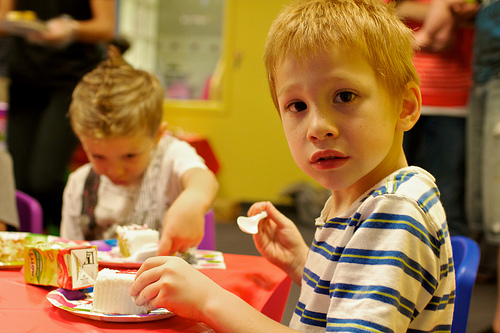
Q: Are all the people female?
A: No, they are both male and female.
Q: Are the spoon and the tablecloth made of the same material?
A: Yes, both the spoon and the tablecloth are made of plastic.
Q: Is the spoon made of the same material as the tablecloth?
A: Yes, both the spoon and the tablecloth are made of plastic.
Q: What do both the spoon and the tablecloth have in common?
A: The material, both the spoon and the tablecloth are plastic.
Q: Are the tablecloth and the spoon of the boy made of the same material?
A: Yes, both the tablecloth and the spoon are made of plastic.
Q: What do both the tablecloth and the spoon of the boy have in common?
A: The material, both the tablecloth and the spoon are plastic.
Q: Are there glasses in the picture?
A: No, there are no glasses.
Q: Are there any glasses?
A: No, there are no glasses.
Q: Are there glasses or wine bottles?
A: No, there are no glasses or wine bottles.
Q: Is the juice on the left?
A: Yes, the juice is on the left of the image.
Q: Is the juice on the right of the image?
A: No, the juice is on the left of the image.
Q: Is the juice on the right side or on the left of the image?
A: The juice is on the left of the image.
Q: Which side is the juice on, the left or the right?
A: The juice is on the left of the image.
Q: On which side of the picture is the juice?
A: The juice is on the left of the image.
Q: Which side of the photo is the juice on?
A: The juice is on the left of the image.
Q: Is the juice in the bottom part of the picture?
A: Yes, the juice is in the bottom of the image.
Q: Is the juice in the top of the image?
A: No, the juice is in the bottom of the image.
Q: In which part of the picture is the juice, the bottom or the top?
A: The juice is in the bottom of the image.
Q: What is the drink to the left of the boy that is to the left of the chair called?
A: The drink is juice.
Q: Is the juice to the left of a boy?
A: Yes, the juice is to the left of a boy.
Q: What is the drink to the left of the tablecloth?
A: The drink is juice.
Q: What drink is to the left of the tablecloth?
A: The drink is juice.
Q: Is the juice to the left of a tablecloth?
A: Yes, the juice is to the left of a tablecloth.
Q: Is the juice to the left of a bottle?
A: No, the juice is to the left of a tablecloth.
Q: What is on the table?
A: The juice is on the table.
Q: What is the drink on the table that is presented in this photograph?
A: The drink is juice.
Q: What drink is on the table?
A: The drink is juice.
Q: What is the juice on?
A: The juice is on the table.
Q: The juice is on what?
A: The juice is on the table.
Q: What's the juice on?
A: The juice is on the table.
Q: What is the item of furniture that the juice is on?
A: The piece of furniture is a table.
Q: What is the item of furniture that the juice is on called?
A: The piece of furniture is a table.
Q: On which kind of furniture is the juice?
A: The juice is on the table.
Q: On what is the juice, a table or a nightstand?
A: The juice is on a table.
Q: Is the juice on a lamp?
A: No, the juice is on the table.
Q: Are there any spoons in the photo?
A: Yes, there is a spoon.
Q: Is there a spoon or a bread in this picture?
A: Yes, there is a spoon.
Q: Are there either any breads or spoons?
A: Yes, there is a spoon.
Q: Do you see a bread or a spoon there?
A: Yes, there is a spoon.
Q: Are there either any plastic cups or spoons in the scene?
A: Yes, there is a plastic spoon.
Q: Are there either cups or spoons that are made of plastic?
A: Yes, the spoon is made of plastic.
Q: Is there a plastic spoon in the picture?
A: Yes, there is a spoon that is made of plastic.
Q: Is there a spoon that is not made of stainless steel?
A: Yes, there is a spoon that is made of plastic.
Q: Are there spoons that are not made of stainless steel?
A: Yes, there is a spoon that is made of plastic.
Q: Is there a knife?
A: No, there are no knives.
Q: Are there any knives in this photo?
A: No, there are no knives.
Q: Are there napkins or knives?
A: No, there are no knives or napkins.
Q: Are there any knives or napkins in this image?
A: No, there are no knives or napkins.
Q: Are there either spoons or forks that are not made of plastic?
A: No, there is a spoon but it is made of plastic.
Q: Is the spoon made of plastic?
A: Yes, the spoon is made of plastic.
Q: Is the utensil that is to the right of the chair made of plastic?
A: Yes, the spoon is made of plastic.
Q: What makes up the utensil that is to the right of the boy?
A: The spoon is made of plastic.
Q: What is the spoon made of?
A: The spoon is made of plastic.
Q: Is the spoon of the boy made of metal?
A: No, the spoon is made of plastic.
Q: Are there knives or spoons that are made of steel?
A: No, there is a spoon but it is made of plastic.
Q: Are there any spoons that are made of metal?
A: No, there is a spoon but it is made of plastic.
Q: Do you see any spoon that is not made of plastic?
A: No, there is a spoon but it is made of plastic.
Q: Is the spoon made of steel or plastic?
A: The spoon is made of plastic.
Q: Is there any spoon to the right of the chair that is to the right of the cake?
A: Yes, there is a spoon to the right of the chair.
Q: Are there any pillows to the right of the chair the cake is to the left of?
A: No, there is a spoon to the right of the chair.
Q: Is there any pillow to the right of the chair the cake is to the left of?
A: No, there is a spoon to the right of the chair.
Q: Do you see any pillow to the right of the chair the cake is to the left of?
A: No, there is a spoon to the right of the chair.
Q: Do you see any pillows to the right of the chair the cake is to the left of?
A: No, there is a spoon to the right of the chair.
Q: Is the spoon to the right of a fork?
A: No, the spoon is to the right of the chair.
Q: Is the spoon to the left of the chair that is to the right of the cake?
A: No, the spoon is to the right of the chair.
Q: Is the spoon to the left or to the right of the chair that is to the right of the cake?
A: The spoon is to the right of the chair.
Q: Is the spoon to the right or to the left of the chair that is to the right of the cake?
A: The spoon is to the right of the chair.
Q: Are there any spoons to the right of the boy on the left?
A: Yes, there is a spoon to the right of the boy.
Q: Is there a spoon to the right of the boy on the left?
A: Yes, there is a spoon to the right of the boy.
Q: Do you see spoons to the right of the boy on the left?
A: Yes, there is a spoon to the right of the boy.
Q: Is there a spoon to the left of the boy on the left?
A: No, the spoon is to the right of the boy.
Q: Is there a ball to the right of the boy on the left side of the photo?
A: No, there is a spoon to the right of the boy.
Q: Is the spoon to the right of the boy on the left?
A: Yes, the spoon is to the right of the boy.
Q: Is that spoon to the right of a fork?
A: No, the spoon is to the right of the boy.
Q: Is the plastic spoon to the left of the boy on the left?
A: No, the spoon is to the right of the boy.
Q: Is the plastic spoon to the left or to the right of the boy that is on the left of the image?
A: The spoon is to the right of the boy.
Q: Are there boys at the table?
A: Yes, there is a boy at the table.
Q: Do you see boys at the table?
A: Yes, there is a boy at the table.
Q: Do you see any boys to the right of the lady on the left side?
A: Yes, there is a boy to the right of the lady.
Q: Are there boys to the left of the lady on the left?
A: No, the boy is to the right of the lady.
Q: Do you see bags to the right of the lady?
A: No, there is a boy to the right of the lady.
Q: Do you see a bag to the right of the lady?
A: No, there is a boy to the right of the lady.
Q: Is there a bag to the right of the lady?
A: No, there is a boy to the right of the lady.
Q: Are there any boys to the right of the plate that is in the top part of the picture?
A: Yes, there is a boy to the right of the plate.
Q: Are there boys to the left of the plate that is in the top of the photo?
A: No, the boy is to the right of the plate.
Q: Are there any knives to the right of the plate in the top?
A: No, there is a boy to the right of the plate.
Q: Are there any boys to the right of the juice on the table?
A: Yes, there is a boy to the right of the juice.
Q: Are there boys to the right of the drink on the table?
A: Yes, there is a boy to the right of the juice.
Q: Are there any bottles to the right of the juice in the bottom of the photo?
A: No, there is a boy to the right of the juice.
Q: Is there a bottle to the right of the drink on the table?
A: No, there is a boy to the right of the juice.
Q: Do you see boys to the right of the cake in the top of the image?
A: Yes, there is a boy to the right of the cake.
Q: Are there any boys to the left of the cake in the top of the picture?
A: No, the boy is to the right of the cake.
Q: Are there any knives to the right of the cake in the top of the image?
A: No, there is a boy to the right of the cake.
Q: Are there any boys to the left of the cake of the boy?
A: No, the boy is to the right of the cake.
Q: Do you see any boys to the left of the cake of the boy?
A: No, the boy is to the right of the cake.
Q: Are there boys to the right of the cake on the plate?
A: Yes, there is a boy to the right of the cake.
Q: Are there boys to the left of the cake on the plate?
A: No, the boy is to the right of the cake.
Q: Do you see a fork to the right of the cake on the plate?
A: No, there is a boy to the right of the cake.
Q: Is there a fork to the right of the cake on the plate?
A: No, there is a boy to the right of the cake.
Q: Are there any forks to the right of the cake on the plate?
A: No, there is a boy to the right of the cake.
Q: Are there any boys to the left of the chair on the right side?
A: Yes, there is a boy to the left of the chair.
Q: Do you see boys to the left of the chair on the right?
A: Yes, there is a boy to the left of the chair.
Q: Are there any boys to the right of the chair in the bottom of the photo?
A: No, the boy is to the left of the chair.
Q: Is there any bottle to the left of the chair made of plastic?
A: No, there is a boy to the left of the chair.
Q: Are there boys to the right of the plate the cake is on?
A: Yes, there is a boy to the right of the plate.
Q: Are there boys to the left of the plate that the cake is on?
A: No, the boy is to the right of the plate.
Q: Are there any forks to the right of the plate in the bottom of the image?
A: No, there is a boy to the right of the plate.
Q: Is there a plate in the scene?
A: Yes, there is a plate.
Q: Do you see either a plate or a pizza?
A: Yes, there is a plate.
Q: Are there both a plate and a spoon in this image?
A: Yes, there are both a plate and a spoon.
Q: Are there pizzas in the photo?
A: No, there are no pizzas.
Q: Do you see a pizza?
A: No, there are no pizzas.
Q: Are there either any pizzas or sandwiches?
A: No, there are no pizzas or sandwiches.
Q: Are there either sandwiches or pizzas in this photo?
A: No, there are no pizzas or sandwiches.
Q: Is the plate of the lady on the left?
A: Yes, the plate is on the left of the image.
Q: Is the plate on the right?
A: No, the plate is on the left of the image.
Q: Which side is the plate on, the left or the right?
A: The plate is on the left of the image.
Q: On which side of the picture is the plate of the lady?
A: The plate is on the left of the image.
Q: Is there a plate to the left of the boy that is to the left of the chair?
A: Yes, there is a plate to the left of the boy.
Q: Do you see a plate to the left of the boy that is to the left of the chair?
A: Yes, there is a plate to the left of the boy.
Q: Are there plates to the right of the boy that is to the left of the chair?
A: No, the plate is to the left of the boy.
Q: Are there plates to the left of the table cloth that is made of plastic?
A: Yes, there is a plate to the left of the tablecloth.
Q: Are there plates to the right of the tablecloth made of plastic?
A: No, the plate is to the left of the table cloth.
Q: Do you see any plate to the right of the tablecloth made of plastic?
A: No, the plate is to the left of the table cloth.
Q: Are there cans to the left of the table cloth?
A: No, there is a plate to the left of the table cloth.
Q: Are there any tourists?
A: No, there are no tourists.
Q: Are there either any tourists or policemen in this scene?
A: No, there are no tourists or policemen.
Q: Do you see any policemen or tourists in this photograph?
A: No, there are no tourists or policemen.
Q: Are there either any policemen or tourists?
A: No, there are no tourists or policemen.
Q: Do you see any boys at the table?
A: Yes, there is a boy at the table.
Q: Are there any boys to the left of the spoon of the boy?
A: Yes, there is a boy to the left of the spoon.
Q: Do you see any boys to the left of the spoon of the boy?
A: Yes, there is a boy to the left of the spoon.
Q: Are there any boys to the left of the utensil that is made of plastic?
A: Yes, there is a boy to the left of the spoon.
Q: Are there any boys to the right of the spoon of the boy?
A: No, the boy is to the left of the spoon.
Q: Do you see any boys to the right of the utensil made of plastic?
A: No, the boy is to the left of the spoon.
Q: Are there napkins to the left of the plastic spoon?
A: No, there is a boy to the left of the spoon.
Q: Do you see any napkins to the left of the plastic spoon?
A: No, there is a boy to the left of the spoon.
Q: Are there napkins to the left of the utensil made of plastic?
A: No, there is a boy to the left of the spoon.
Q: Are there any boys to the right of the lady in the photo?
A: Yes, there is a boy to the right of the lady.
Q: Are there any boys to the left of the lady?
A: No, the boy is to the right of the lady.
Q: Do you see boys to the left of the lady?
A: No, the boy is to the right of the lady.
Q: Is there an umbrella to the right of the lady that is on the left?
A: No, there is a boy to the right of the lady.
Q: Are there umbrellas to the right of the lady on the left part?
A: No, there is a boy to the right of the lady.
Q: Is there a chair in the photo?
A: Yes, there is a chair.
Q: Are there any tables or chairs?
A: Yes, there is a chair.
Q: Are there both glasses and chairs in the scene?
A: No, there is a chair but no glasses.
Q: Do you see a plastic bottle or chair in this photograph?
A: Yes, there is a plastic chair.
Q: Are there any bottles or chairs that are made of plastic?
A: Yes, the chair is made of plastic.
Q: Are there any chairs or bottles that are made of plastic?
A: Yes, the chair is made of plastic.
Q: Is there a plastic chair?
A: Yes, there is a chair that is made of plastic.